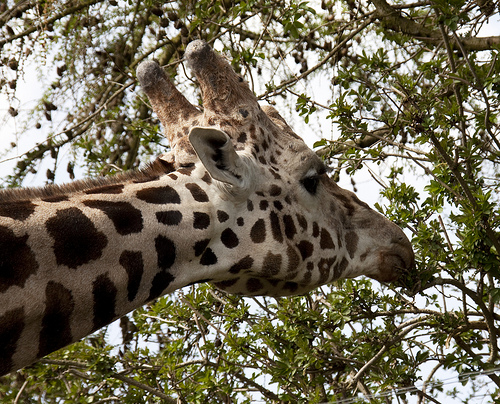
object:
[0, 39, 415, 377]
giraffe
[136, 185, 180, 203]
spot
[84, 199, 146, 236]
spot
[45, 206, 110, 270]
spot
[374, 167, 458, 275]
foilage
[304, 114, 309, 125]
leaf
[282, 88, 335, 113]
branch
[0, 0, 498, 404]
tree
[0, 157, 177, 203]
mane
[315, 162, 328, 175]
marking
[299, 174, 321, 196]
eye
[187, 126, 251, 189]
ear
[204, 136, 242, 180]
inside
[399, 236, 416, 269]
nose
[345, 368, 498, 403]
wire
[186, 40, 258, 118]
horn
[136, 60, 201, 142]
horn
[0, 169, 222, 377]
neck